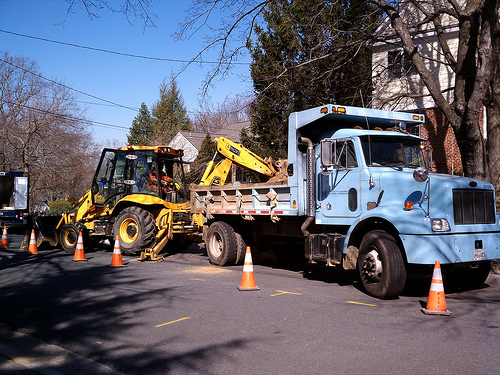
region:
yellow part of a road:
[356, 294, 361, 306]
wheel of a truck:
[378, 246, 397, 276]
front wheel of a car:
[360, 254, 372, 274]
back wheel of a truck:
[211, 242, 221, 252]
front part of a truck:
[462, 191, 474, 205]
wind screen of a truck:
[386, 147, 406, 159]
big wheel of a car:
[139, 195, 144, 225]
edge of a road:
[28, 345, 43, 360]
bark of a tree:
[472, 117, 481, 127]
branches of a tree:
[274, 41, 294, 66]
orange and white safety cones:
[223, 237, 267, 308]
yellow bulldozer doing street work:
[39, 121, 284, 270]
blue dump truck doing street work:
[187, 98, 488, 270]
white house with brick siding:
[382, 8, 489, 163]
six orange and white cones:
[0, 217, 475, 319]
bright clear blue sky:
[72, 43, 122, 85]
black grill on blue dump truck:
[445, 178, 499, 235]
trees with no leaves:
[15, 47, 99, 199]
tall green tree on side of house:
[245, 0, 375, 169]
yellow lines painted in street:
[150, 288, 209, 346]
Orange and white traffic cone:
[423, 258, 451, 315]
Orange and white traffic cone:
[236, 243, 260, 289]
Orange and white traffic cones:
[1, 222, 126, 267]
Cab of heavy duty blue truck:
[299, 113, 496, 258]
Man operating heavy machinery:
[138, 158, 178, 193]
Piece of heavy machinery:
[56, 137, 260, 254]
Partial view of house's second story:
[371, 0, 498, 109]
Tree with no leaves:
[261, 3, 499, 111]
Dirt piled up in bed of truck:
[182, 171, 292, 217]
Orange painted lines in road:
[151, 281, 380, 335]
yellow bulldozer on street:
[58, 134, 258, 263]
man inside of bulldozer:
[140, 160, 180, 205]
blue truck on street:
[213, 101, 490, 306]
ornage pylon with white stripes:
[410, 259, 461, 336]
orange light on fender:
[398, 196, 423, 217]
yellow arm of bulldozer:
[205, 129, 265, 185]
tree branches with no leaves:
[168, 4, 248, 112]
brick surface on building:
[420, 114, 455, 173]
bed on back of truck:
[190, 171, 294, 222]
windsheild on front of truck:
[363, 133, 430, 175]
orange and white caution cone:
[229, 242, 266, 298]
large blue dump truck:
[197, 99, 486, 281]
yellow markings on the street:
[233, 287, 382, 313]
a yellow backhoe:
[56, 136, 222, 239]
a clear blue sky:
[97, 55, 145, 96]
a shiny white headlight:
[429, 207, 456, 236]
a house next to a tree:
[376, 30, 441, 111]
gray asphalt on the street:
[203, 317, 257, 373]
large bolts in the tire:
[364, 254, 374, 279]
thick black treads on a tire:
[226, 231, 235, 258]